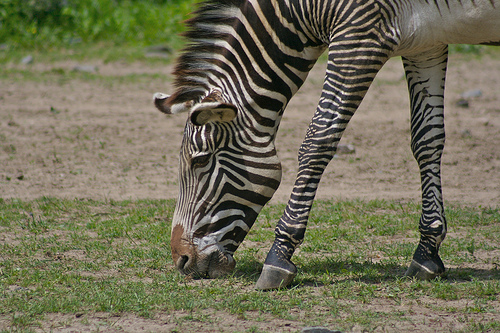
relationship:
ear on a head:
[189, 101, 241, 128] [154, 86, 283, 282]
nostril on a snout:
[174, 253, 192, 270] [168, 235, 205, 283]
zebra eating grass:
[151, 0, 498, 290] [30, 209, 168, 307]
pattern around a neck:
[247, 11, 291, 95] [175, 1, 319, 138]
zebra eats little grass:
[151, 0, 498, 290] [152, 277, 240, 317]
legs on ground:
[253, 38, 450, 292] [0, 5, 497, 325]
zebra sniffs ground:
[151, 0, 500, 292] [23, 67, 484, 305]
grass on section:
[0, 198, 497, 330] [7, 200, 473, 326]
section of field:
[7, 200, 473, 326] [4, 47, 498, 324]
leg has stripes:
[396, 57, 452, 282] [409, 104, 429, 130]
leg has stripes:
[396, 57, 452, 282] [409, 127, 449, 139]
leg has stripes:
[396, 57, 452, 282] [423, 206, 437, 216]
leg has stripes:
[396, 57, 452, 282] [417, 237, 439, 256]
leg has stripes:
[396, 57, 452, 282] [416, 172, 433, 188]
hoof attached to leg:
[250, 252, 302, 295] [252, 24, 401, 295]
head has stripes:
[124, 71, 321, 267] [194, 144, 273, 238]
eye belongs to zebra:
[188, 150, 217, 170] [151, 0, 498, 290]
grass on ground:
[0, 197, 500, 332] [0, 5, 497, 325]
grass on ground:
[0, 197, 500, 332] [24, 85, 162, 302]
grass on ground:
[0, 197, 500, 332] [12, 60, 467, 327]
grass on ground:
[1, 1, 494, 84] [0, 5, 497, 325]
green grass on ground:
[60, 206, 125, 273] [10, 205, 484, 318]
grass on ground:
[0, 197, 500, 332] [5, 214, 478, 314]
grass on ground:
[0, 198, 497, 330] [0, 40, 499, 329]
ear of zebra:
[189, 101, 236, 123] [151, 0, 498, 290]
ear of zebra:
[152, 93, 188, 113] [151, 0, 498, 290]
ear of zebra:
[189, 101, 241, 128] [151, 0, 498, 290]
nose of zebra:
[165, 222, 232, 276] [59, 24, 482, 319]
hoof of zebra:
[254, 256, 299, 291] [151, 0, 498, 290]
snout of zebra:
[145, 216, 262, 303] [151, 0, 498, 290]